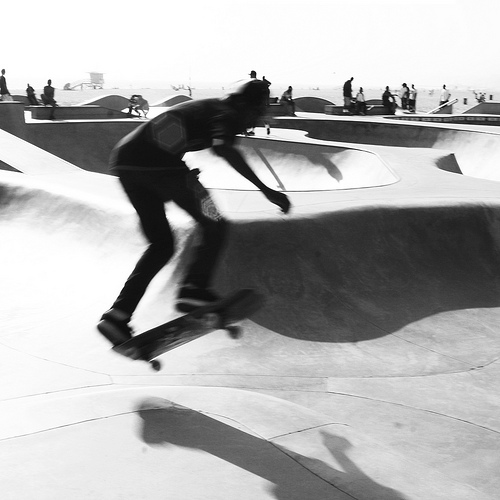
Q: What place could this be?
A: It is a skate park.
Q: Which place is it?
A: It is a skate park.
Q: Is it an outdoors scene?
A: Yes, it is outdoors.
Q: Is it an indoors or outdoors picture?
A: It is outdoors.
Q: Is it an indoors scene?
A: No, it is outdoors.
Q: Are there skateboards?
A: Yes, there is a skateboard.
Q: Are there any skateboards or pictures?
A: Yes, there is a skateboard.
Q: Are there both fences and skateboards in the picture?
A: No, there is a skateboard but no fences.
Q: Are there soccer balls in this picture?
A: No, there are no soccer balls.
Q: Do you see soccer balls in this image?
A: No, there are no soccer balls.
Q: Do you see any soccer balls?
A: No, there are no soccer balls.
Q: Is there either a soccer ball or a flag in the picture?
A: No, there are no soccer balls or flags.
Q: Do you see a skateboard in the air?
A: Yes, there is a skateboard in the air.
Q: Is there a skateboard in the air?
A: Yes, there is a skateboard in the air.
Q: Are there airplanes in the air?
A: No, there is a skateboard in the air.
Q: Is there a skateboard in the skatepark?
A: Yes, there is a skateboard in the skatepark.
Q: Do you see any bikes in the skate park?
A: No, there is a skateboard in the skate park.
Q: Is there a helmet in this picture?
A: No, there are no helmets.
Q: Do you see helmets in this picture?
A: No, there are no helmets.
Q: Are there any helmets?
A: No, there are no helmets.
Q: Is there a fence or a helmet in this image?
A: No, there are no helmets or fences.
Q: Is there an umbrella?
A: No, there are no umbrellas.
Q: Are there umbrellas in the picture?
A: No, there are no umbrellas.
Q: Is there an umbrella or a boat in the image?
A: No, there are no umbrellas or boats.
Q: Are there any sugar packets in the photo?
A: No, there are no sugar packets.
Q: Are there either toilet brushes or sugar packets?
A: No, there are no sugar packets or toilet brushes.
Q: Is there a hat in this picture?
A: Yes, there is a hat.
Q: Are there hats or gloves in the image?
A: Yes, there is a hat.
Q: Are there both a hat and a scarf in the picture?
A: No, there is a hat but no scarves.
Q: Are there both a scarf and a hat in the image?
A: No, there is a hat but no scarves.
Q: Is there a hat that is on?
A: Yes, there is a hat that is on.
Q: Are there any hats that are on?
A: Yes, there is a hat that is on.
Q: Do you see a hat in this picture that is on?
A: Yes, there is a hat that is on.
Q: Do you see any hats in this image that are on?
A: Yes, there is a hat that is on.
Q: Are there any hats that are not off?
A: Yes, there is a hat that is on.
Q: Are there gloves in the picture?
A: No, there are no gloves.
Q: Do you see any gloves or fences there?
A: No, there are no gloves or fences.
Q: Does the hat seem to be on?
A: Yes, the hat is on.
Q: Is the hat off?
A: No, the hat is on.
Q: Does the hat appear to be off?
A: No, the hat is on.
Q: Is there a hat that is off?
A: No, there is a hat but it is on.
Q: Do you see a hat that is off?
A: No, there is a hat but it is on.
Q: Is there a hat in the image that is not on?
A: No, there is a hat but it is on.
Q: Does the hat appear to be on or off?
A: The hat is on.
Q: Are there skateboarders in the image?
A: Yes, there is a skateboarder.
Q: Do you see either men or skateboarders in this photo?
A: Yes, there is a skateboarder.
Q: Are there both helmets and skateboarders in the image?
A: No, there is a skateboarder but no helmets.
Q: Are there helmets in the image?
A: No, there are no helmets.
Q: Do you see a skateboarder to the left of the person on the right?
A: Yes, there is a skateboarder to the left of the person.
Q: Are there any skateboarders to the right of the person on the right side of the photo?
A: No, the skateboarder is to the left of the person.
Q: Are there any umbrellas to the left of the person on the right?
A: No, there is a skateboarder to the left of the person.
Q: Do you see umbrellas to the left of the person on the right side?
A: No, there is a skateboarder to the left of the person.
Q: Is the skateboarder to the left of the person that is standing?
A: Yes, the skateboarder is to the left of the person.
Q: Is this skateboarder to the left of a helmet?
A: No, the skateboarder is to the left of the person.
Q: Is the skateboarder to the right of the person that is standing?
A: No, the skateboarder is to the left of the person.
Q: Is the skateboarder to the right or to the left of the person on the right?
A: The skateboarder is to the left of the person.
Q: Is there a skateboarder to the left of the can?
A: Yes, there is a skateboarder to the left of the can.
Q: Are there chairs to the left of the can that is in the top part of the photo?
A: No, there is a skateboarder to the left of the can.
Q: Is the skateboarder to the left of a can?
A: Yes, the skateboarder is to the left of a can.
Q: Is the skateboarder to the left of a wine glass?
A: No, the skateboarder is to the left of a can.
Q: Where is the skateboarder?
A: The skateboarder is in the skate park.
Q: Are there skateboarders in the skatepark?
A: Yes, there is a skateboarder in the skatepark.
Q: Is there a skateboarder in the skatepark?
A: Yes, there is a skateboarder in the skatepark.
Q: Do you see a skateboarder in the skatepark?
A: Yes, there is a skateboarder in the skatepark.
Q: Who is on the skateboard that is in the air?
A: The skateboarder is on the skateboard.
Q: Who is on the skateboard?
A: The skateboarder is on the skateboard.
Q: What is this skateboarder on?
A: The skateboarder is on the skateboard.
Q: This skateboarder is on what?
A: The skateboarder is on the skateboard.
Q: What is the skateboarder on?
A: The skateboarder is on the skateboard.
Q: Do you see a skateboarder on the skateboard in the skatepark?
A: Yes, there is a skateboarder on the skateboard.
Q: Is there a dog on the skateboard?
A: No, there is a skateboarder on the skateboard.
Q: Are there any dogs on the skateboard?
A: No, there is a skateboarder on the skateboard.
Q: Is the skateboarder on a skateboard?
A: Yes, the skateboarder is on a skateboard.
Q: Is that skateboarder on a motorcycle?
A: No, the skateboarder is on a skateboard.